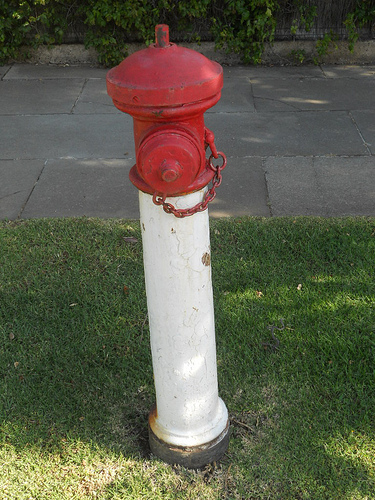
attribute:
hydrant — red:
[115, 15, 241, 457]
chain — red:
[154, 159, 229, 218]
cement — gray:
[238, 81, 375, 210]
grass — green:
[233, 225, 373, 434]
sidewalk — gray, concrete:
[238, 67, 371, 221]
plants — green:
[88, 4, 147, 56]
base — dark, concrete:
[142, 421, 242, 468]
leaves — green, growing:
[229, 1, 362, 61]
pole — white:
[136, 189, 235, 447]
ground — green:
[1, 218, 364, 499]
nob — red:
[136, 129, 208, 196]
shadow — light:
[232, 74, 374, 108]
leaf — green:
[105, 33, 120, 48]